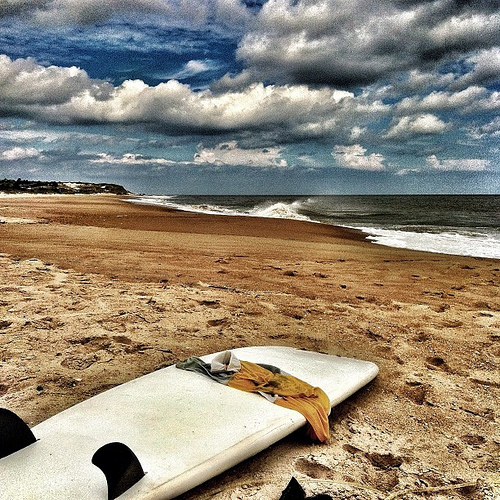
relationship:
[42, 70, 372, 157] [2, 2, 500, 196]
cloud in sky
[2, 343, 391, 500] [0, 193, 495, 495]
surfboard on beach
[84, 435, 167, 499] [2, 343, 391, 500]
fin on surfboard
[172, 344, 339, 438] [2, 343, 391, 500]
clothes on surfboard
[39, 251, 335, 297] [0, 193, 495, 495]
sand on beach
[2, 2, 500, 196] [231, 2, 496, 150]
sky with clouds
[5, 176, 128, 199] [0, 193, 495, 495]
outcropping on beach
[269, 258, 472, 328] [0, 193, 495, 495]
footprints on beach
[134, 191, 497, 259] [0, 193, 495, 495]
ocean at beach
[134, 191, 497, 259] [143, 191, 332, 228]
ocean has waves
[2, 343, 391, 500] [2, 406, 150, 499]
surfboard with fins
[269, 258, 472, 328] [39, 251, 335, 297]
footprints in sand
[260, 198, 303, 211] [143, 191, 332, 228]
caps on waves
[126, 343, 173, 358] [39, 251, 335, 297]
sticks on sand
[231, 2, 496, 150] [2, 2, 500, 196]
clouds against sky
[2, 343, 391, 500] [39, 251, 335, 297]
surfboard in sand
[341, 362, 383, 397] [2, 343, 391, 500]
edge of surfboard